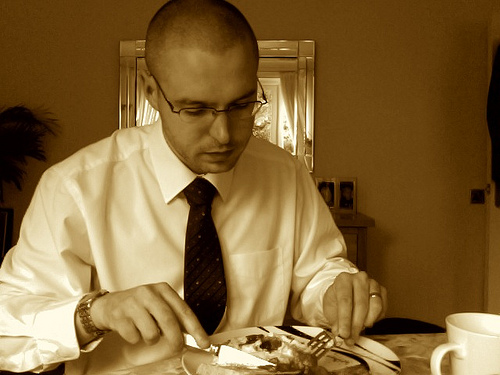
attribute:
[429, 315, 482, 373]
cup — white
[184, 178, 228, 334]
tie — tark, neck, dark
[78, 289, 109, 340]
watch — gold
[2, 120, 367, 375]
shirt — white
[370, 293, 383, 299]
ring — gold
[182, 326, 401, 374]
plate — white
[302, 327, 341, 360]
fork — silver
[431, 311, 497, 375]
mug — white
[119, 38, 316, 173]
frame — silver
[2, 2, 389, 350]
man — sitting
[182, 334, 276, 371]
knife — metal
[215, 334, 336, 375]
food — being cut